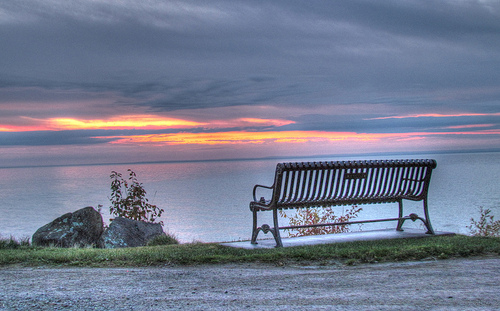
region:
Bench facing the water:
[250, 145, 442, 250]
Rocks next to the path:
[26, 200, 176, 247]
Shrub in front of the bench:
[280, 206, 369, 236]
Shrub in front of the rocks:
[101, 167, 161, 220]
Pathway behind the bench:
[1, 253, 499, 308]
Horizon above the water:
[0, 114, 498, 162]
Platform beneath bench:
[224, 224, 453, 252]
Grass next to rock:
[0, 239, 37, 251]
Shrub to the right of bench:
[464, 205, 499, 235]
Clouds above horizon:
[2, 0, 497, 102]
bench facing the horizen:
[228, 105, 468, 259]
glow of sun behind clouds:
[18, 93, 320, 158]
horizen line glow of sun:
[12, 129, 259, 173]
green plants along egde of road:
[11, 250, 219, 284]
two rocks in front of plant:
[23, 195, 189, 257]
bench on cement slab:
[230, 151, 447, 253]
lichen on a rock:
[45, 208, 95, 243]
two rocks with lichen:
[27, 198, 181, 260]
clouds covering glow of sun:
[18, 75, 492, 152]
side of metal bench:
[240, 149, 295, 256]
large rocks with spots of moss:
[30, 203, 171, 250]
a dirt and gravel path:
[1, 264, 493, 309]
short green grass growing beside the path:
[2, 235, 498, 271]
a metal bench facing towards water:
[249, 158, 438, 250]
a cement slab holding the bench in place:
[219, 223, 456, 253]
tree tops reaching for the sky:
[104, 167, 499, 239]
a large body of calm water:
[2, 150, 498, 243]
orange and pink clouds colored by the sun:
[0, 107, 499, 150]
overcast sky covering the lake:
[2, 3, 496, 155]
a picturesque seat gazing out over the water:
[25, 102, 460, 251]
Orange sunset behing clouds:
[4, 57, 495, 149]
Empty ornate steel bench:
[247, 149, 442, 252]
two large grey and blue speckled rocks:
[31, 206, 174, 256]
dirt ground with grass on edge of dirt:
[8, 239, 499, 309]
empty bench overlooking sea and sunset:
[7, 51, 495, 274]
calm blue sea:
[8, 147, 225, 244]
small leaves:
[467, 200, 497, 242]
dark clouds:
[31, 20, 199, 105]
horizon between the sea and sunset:
[22, 82, 417, 164]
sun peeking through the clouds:
[21, 81, 278, 153]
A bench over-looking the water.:
[252, 157, 435, 242]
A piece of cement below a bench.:
[212, 227, 452, 251]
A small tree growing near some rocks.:
[109, 169, 164, 253]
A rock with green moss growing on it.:
[29, 205, 105, 255]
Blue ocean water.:
[2, 151, 496, 236]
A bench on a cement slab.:
[210, 157, 455, 251]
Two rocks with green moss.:
[27, 205, 171, 251]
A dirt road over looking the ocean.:
[1, 256, 498, 309]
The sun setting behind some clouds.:
[3, 101, 498, 152]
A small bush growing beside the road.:
[467, 208, 499, 244]